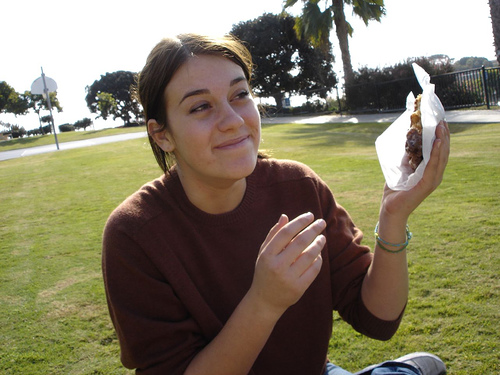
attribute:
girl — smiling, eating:
[127, 20, 377, 318]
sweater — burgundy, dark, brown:
[130, 214, 206, 310]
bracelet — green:
[381, 244, 406, 256]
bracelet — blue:
[390, 240, 403, 248]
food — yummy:
[404, 113, 427, 167]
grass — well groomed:
[437, 249, 475, 304]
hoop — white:
[23, 74, 64, 96]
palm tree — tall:
[305, 2, 363, 82]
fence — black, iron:
[455, 71, 498, 105]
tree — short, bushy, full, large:
[352, 66, 390, 111]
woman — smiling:
[114, 35, 301, 223]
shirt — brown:
[262, 184, 312, 209]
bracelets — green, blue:
[373, 227, 416, 259]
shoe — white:
[401, 351, 449, 374]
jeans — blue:
[350, 366, 413, 373]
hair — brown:
[154, 45, 190, 61]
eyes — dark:
[192, 96, 252, 111]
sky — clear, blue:
[124, 1, 202, 25]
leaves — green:
[293, 12, 333, 51]